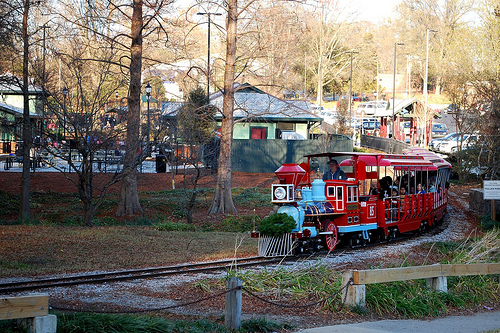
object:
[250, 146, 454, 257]
train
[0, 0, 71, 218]
tree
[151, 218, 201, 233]
grass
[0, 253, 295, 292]
tracks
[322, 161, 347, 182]
guard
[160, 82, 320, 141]
house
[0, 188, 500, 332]
rocks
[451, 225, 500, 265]
weeds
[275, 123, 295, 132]
window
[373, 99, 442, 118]
roof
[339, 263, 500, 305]
fence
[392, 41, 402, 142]
pole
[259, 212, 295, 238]
wreath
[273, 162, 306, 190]
smoke stack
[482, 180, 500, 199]
sign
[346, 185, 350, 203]
window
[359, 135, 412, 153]
tram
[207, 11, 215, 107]
lamp post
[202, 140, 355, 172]
fence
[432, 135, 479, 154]
cars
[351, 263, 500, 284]
railing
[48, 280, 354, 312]
chain